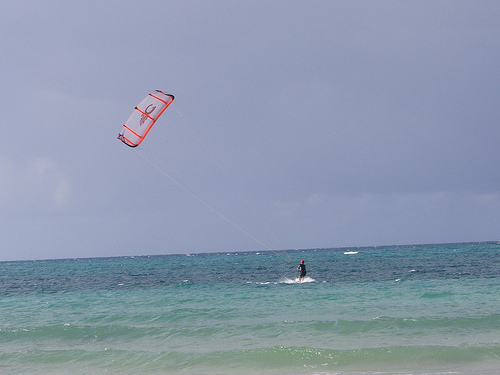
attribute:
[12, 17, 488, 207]
sky — blue, clear, gray, hazy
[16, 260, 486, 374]
ocean — blue, wet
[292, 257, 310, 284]
man — surfing, windsurfing, alone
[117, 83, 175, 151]
parasail — flying, gray, large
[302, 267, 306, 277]
wetsuit — black